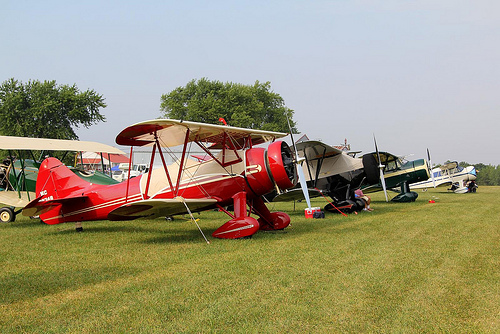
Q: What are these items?
A: Airplanes.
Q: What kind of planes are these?
A: Bi-planes.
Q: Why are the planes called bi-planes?
A: Two sets of wings.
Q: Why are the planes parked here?
A: On display.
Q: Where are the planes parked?
A: Field.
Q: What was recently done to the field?
A: Grass was cut.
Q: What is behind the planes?
A: Trees.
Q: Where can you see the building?
A: Behind the plains.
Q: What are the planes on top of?
A: A field of grass.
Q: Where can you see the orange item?
A: In Front of plane on grass.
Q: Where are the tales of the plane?
A: On the back of plane.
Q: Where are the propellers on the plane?
A: In the front of the plane.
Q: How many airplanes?
A: Four.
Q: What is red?
A: Airplane.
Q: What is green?
A: Grass.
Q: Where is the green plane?
A: Third one in the row.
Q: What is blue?
A: Sky.